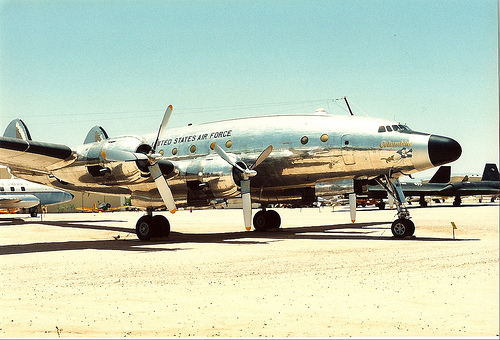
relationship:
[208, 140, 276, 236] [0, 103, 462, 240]
propeller on side of plane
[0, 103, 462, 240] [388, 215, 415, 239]
plane has wheel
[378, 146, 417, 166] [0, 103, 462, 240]
graphic on side of plane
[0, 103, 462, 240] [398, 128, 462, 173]
plane has nose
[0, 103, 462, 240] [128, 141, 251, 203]
plane has engine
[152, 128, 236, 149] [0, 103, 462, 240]
writing on side of plane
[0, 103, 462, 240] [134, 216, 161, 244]
plane has back wheel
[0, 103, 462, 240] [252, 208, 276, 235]
plane has back wheel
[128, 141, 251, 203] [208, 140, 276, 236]
engine has propeller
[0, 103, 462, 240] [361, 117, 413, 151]
plane has cockpit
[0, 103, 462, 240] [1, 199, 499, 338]
plane on top of runway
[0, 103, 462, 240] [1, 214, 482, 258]
plane has shadow